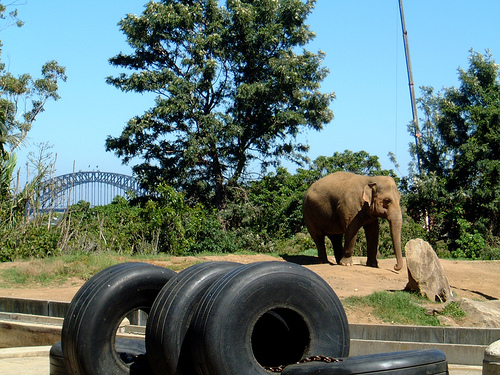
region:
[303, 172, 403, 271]
Elephant standing in the dirt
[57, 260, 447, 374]
Four rubber tires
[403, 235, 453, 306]
Tree stump in front of elephant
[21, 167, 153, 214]
Bridge in the distance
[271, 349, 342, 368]
Chain on the tires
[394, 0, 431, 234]
Tall post behind the trees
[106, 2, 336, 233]
Tree behind the elephant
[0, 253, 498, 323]
Grass and dirt on the ground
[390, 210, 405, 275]
Elephant's trunk touching the ground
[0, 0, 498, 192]
Cloudless blue sky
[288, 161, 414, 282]
the elephant is brown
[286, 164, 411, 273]
the elephant is brown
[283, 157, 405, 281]
the elephant is brown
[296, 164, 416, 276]
the elephant is brown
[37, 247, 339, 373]
the tires are black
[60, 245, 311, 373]
the tires are black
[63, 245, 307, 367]
the tires are black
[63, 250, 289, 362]
the tires are black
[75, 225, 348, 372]
the tires are black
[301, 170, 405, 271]
a standing grey elephant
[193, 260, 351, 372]
a large black tire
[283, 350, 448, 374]
a large black tire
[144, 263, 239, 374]
a large black tire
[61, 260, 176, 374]
a large black tire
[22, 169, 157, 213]
a bridge in distance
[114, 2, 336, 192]
large green tree in distance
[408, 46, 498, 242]
large green tree in distance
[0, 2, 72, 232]
large green tree in distance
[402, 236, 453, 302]
a large brown tree stump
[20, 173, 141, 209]
a bridge behind the trees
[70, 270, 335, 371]
black tires on the ground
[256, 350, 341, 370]
a chain on the tires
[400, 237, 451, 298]
a rock in front of the elephant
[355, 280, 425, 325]
grass next to the rock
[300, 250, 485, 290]
dirt under the elephant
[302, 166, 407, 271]
an elephant standing on dirt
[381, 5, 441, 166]
a pole behind the elephant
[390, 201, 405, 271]
the trunk of the elephant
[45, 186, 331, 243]
bushes behind the elephant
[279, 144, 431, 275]
this is an elephant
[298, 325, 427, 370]
this is a wheel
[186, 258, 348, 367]
this is a wheel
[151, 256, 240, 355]
this is a wheel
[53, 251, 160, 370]
this is a wheel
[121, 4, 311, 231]
this is a tree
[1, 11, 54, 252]
this is a tree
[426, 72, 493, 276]
this is a tree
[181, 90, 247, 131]
green leaves on the tree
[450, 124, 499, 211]
green leaves on the tree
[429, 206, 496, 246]
green leaves on the tree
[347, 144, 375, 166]
green leaves on the tree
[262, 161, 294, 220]
green leaves on the tree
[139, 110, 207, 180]
green leaves on the tree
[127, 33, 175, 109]
green leaves on the tree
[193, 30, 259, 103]
green leaves on the tree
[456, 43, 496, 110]
green leaves on the tree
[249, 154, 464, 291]
elephant on the ground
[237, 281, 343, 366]
hole in the wheel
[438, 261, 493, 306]
dirt in front of elephant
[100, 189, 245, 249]
trees behind the elephant